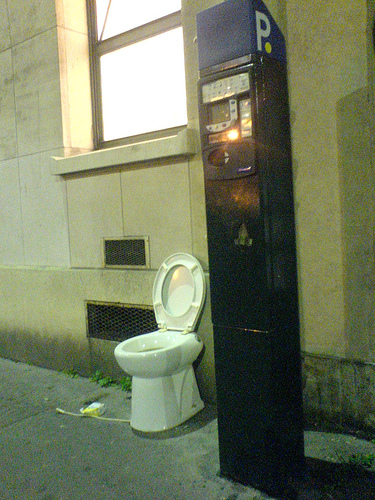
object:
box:
[81, 402, 109, 415]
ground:
[2, 357, 132, 498]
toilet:
[113, 252, 207, 433]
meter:
[198, 1, 293, 478]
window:
[86, 10, 184, 151]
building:
[4, 0, 371, 359]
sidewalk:
[1, 357, 374, 499]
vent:
[100, 238, 148, 269]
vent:
[84, 303, 158, 341]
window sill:
[56, 132, 195, 176]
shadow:
[302, 457, 373, 499]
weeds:
[65, 369, 92, 381]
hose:
[54, 411, 132, 424]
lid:
[151, 253, 206, 333]